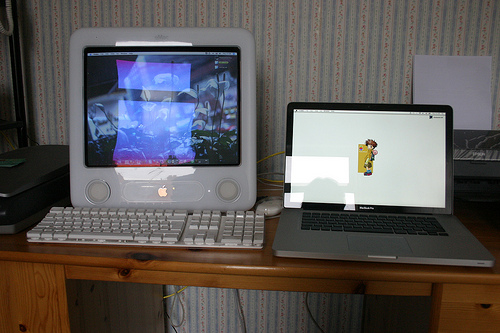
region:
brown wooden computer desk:
[1, 195, 499, 330]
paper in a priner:
[410, 49, 497, 141]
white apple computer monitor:
[66, 21, 257, 212]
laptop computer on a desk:
[271, 97, 496, 270]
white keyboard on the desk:
[24, 200, 266, 257]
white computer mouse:
[252, 192, 287, 219]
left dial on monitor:
[85, 175, 113, 207]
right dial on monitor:
[210, 176, 246, 206]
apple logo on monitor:
[153, 182, 170, 199]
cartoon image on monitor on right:
[351, 134, 381, 182]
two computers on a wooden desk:
[17, 22, 499, 287]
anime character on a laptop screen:
[356, 138, 377, 180]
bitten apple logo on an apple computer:
[156, 184, 169, 198]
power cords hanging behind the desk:
[161, 279, 335, 331]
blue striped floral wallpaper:
[258, 0, 409, 102]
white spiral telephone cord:
[1, 0, 15, 37]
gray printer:
[450, 124, 499, 213]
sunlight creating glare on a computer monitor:
[111, 38, 198, 184]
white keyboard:
[23, 200, 267, 256]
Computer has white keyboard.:
[51, 192, 268, 272]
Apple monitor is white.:
[63, 46, 244, 220]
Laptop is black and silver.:
[306, 147, 496, 331]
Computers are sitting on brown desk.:
[59, 179, 469, 299]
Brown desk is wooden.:
[37, 161, 400, 298]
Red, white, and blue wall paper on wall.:
[271, 18, 392, 78]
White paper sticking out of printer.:
[390, 40, 498, 113]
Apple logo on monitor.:
[143, 176, 195, 225]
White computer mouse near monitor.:
[256, 175, 285, 251]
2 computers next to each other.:
[85, 56, 397, 309]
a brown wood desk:
[5, 186, 495, 324]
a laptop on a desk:
[273, 94, 487, 268]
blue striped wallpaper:
[30, 3, 498, 158]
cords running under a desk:
[161, 282, 352, 327]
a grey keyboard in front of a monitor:
[20, 190, 268, 256]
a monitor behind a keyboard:
[58, 17, 274, 209]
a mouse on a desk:
[254, 186, 288, 219]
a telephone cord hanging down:
[0, 4, 25, 34]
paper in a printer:
[405, 46, 493, 130]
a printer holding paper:
[452, 100, 499, 204]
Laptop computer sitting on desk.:
[273, 91, 492, 273]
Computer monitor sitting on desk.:
[61, 25, 268, 210]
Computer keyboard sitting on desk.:
[27, 197, 264, 260]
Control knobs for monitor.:
[80, 173, 245, 208]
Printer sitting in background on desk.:
[455, 128, 499, 197]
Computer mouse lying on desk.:
[253, 190, 285, 223]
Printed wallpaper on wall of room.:
[270, 11, 402, 98]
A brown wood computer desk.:
[1, 247, 497, 332]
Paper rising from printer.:
[412, 52, 499, 131]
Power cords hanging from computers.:
[169, 287, 361, 331]